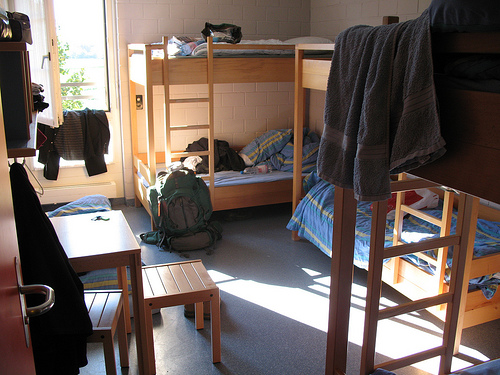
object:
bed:
[323, 16, 500, 375]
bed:
[127, 36, 336, 234]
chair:
[140, 258, 220, 374]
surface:
[43, 208, 142, 259]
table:
[45, 208, 152, 374]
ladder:
[163, 35, 215, 216]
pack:
[138, 164, 223, 260]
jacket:
[8, 162, 92, 374]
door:
[0, 96, 55, 374]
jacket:
[77, 108, 110, 179]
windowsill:
[64, 108, 111, 116]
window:
[0, 0, 111, 114]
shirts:
[0, 9, 33, 148]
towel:
[316, 22, 405, 203]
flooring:
[47, 205, 499, 374]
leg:
[211, 300, 222, 364]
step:
[168, 97, 211, 106]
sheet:
[135, 162, 313, 191]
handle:
[20, 283, 55, 318]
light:
[54, 1, 110, 112]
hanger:
[22, 158, 45, 196]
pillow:
[238, 128, 294, 167]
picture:
[0, 2, 497, 374]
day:
[2, 3, 496, 372]